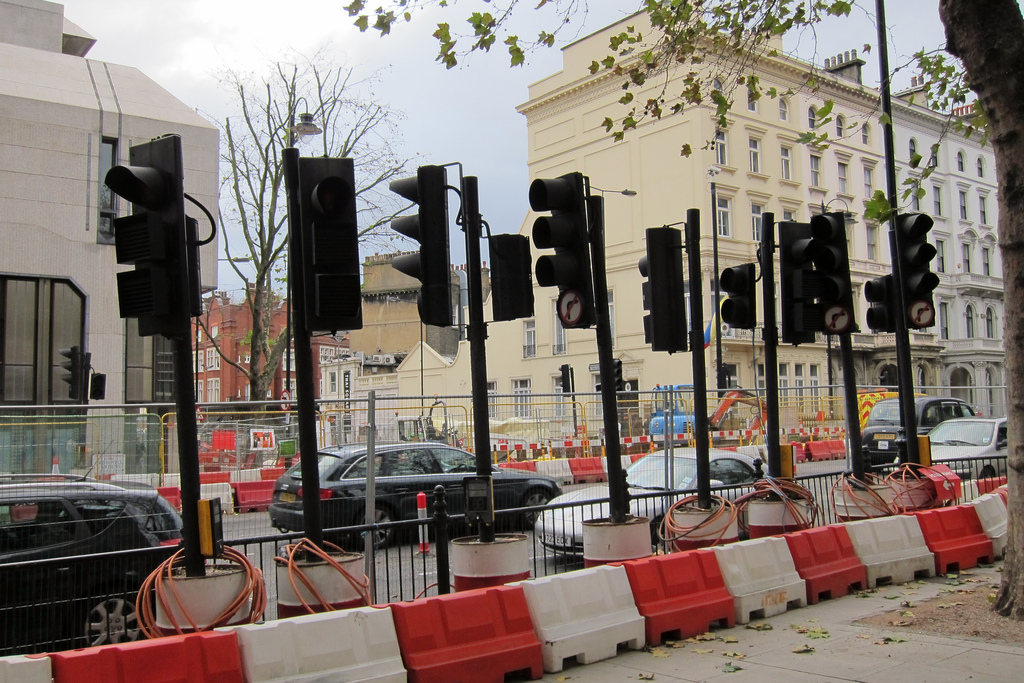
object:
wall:
[345, 326, 529, 503]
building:
[345, 247, 529, 503]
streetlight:
[101, 133, 199, 339]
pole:
[106, 132, 210, 576]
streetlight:
[287, 157, 361, 331]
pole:
[291, 144, 359, 557]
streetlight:
[386, 166, 451, 328]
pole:
[388, 165, 495, 544]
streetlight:
[528, 172, 615, 328]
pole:
[521, 173, 631, 525]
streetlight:
[636, 227, 686, 356]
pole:
[640, 203, 709, 509]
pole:
[725, 212, 783, 486]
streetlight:
[718, 263, 754, 328]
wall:
[362, 285, 420, 346]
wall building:
[402, 575, 594, 669]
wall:
[323, 5, 715, 472]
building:
[323, 0, 1024, 463]